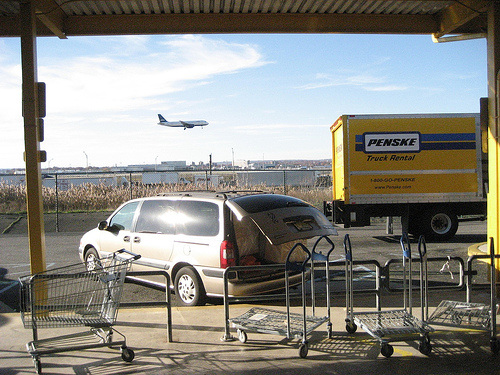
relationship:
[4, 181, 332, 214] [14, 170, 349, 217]
grass in field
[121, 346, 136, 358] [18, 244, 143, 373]
wheel of shopping cart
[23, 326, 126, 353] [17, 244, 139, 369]
rack under cart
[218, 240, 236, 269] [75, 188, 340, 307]
light at back of car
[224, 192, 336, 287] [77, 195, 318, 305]
door at rear of van